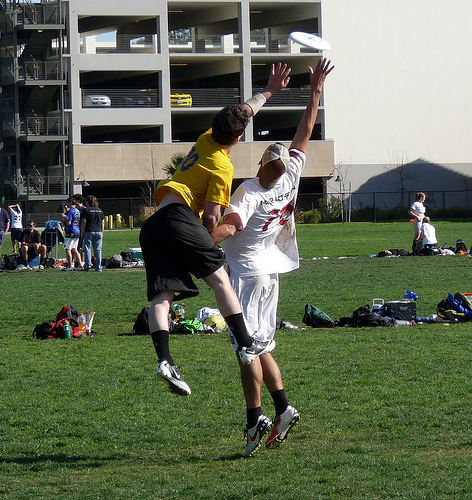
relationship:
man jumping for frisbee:
[138, 63, 293, 400] [286, 27, 331, 55]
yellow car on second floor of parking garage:
[185, 139, 208, 155] [4, 0, 335, 230]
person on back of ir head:
[7, 200, 25, 260] [7, 202, 23, 214]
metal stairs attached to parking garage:
[2, 51, 42, 87] [4, 0, 335, 230]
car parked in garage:
[76, 77, 158, 132] [26, 12, 303, 200]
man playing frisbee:
[210, 55, 335, 460] [275, 15, 343, 56]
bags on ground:
[305, 294, 467, 330] [24, 364, 92, 435]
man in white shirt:
[228, 140, 316, 459] [226, 148, 305, 286]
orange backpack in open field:
[53, 302, 100, 340] [0, 218, 469, 498]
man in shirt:
[101, 66, 378, 459] [151, 139, 231, 197]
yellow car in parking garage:
[168, 91, 193, 107] [67, 0, 335, 184]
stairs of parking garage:
[4, 1, 74, 203] [66, 1, 335, 227]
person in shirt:
[81, 182, 120, 285] [236, 172, 312, 253]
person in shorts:
[81, 182, 120, 285] [228, 255, 306, 358]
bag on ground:
[300, 297, 337, 332] [22, 184, 454, 484]